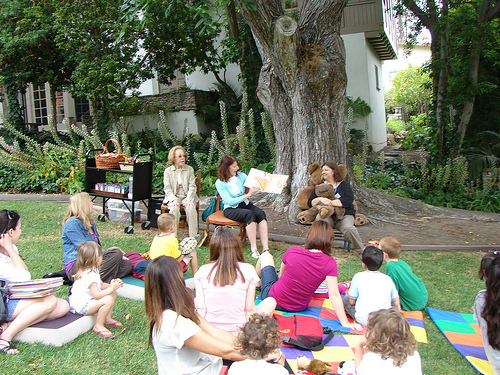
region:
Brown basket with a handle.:
[96, 138, 126, 169]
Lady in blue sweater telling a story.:
[210, 154, 289, 249]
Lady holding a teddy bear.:
[296, 156, 367, 250]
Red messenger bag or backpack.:
[268, 313, 336, 355]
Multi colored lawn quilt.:
[427, 306, 482, 373]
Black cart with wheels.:
[83, 141, 153, 233]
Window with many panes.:
[23, 80, 89, 132]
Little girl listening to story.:
[71, 240, 121, 340]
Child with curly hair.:
[228, 312, 289, 374]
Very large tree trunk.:
[238, 2, 350, 170]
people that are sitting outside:
[84, 116, 434, 369]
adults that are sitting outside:
[79, 191, 304, 370]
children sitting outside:
[82, 216, 382, 371]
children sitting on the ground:
[39, 198, 344, 374]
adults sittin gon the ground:
[21, 198, 306, 308]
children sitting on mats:
[134, 214, 382, 373]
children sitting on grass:
[102, 216, 369, 370]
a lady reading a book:
[185, 123, 370, 333]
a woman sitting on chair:
[137, 116, 226, 263]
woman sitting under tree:
[269, 108, 456, 374]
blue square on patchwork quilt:
[428, 306, 463, 324]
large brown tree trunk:
[275, 92, 345, 164]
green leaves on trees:
[53, 20, 102, 74]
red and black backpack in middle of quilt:
[277, 313, 337, 355]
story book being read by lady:
[241, 145, 300, 212]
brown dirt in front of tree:
[437, 215, 487, 238]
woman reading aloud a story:
[212, 150, 259, 246]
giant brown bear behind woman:
[306, 160, 373, 250]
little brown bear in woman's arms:
[308, 182, 343, 221]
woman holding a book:
[210, 151, 290, 216]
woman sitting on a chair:
[160, 140, 201, 210]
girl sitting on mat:
[280, 216, 345, 312]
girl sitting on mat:
[200, 223, 253, 303]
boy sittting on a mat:
[353, 241, 394, 306]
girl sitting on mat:
[368, 305, 409, 361]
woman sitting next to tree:
[307, 155, 354, 207]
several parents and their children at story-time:
[6, 133, 490, 369]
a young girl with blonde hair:
[68, 240, 121, 339]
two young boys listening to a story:
[341, 229, 432, 307]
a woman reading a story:
[212, 153, 287, 258]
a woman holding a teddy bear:
[312, 158, 361, 227]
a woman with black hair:
[1, 201, 69, 355]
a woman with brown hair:
[140, 255, 215, 367]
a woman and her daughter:
[1, 206, 121, 352]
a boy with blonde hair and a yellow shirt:
[146, 206, 201, 277]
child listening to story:
[72, 243, 128, 344]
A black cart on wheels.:
[75, 140, 151, 233]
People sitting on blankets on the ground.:
[0, 187, 498, 373]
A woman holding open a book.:
[215, 151, 296, 261]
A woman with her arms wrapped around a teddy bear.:
[307, 163, 367, 249]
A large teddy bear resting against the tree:
[293, 162, 364, 229]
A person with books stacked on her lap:
[2, 208, 70, 358]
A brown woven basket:
[95, 136, 125, 168]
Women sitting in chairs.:
[155, 148, 365, 253]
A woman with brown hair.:
[257, 220, 354, 322]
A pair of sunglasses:
[0, 206, 13, 238]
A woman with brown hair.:
[142, 248, 239, 373]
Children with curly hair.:
[236, 300, 427, 374]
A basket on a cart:
[89, 137, 131, 168]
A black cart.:
[71, 141, 151, 230]